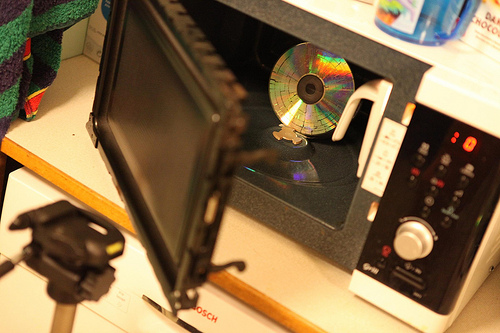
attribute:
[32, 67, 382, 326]
table — white, wood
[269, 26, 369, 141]
cd — reflective, cracked, shiny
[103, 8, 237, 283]
door — black, open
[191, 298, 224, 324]
logo — written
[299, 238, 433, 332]
edge — wood, yellow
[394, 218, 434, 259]
knob — silver, white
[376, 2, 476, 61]
container — blue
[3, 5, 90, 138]
towel — green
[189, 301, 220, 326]
word — bosch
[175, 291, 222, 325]
word — bosch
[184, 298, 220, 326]
word — bosch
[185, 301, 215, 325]
word — bosch